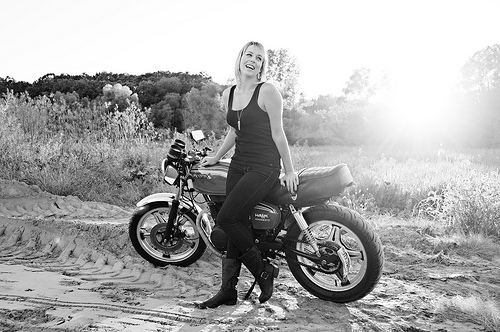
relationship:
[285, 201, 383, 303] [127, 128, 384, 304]
black tire on motorcycle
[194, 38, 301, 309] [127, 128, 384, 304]
woman on motorcycle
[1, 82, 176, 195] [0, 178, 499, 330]
bushes along roadside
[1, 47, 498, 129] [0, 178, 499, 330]
trees along roadside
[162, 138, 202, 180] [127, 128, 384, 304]
handle bars on motorcycle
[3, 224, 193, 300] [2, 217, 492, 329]
tire tracks on dirt road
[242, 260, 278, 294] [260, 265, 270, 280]
boots have buckle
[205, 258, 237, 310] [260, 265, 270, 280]
boots have buckle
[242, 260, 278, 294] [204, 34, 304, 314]
boots worn by woman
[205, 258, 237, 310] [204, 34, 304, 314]
boots worn by woman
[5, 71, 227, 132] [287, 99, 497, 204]
trees behind field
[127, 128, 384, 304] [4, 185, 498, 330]
motorcycle on road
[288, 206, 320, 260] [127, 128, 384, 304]
shock on motorcycle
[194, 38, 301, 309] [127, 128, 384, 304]
woman in front of motorcycle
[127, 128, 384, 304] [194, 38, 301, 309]
motorcycle behind woman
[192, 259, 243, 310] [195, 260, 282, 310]
boots on feet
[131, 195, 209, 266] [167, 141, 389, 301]
tire on motorcycle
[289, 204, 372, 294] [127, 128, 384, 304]
tire of motorcycle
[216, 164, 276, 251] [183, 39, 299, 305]
pants on woman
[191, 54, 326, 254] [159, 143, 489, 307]
lady near motorcycle